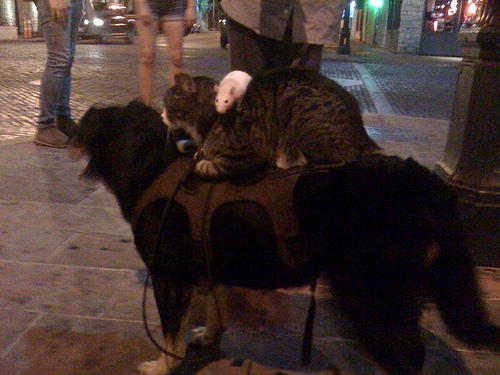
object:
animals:
[102, 66, 473, 320]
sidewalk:
[0, 269, 325, 374]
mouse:
[208, 69, 252, 115]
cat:
[156, 64, 379, 180]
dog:
[45, 95, 500, 375]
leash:
[144, 175, 197, 362]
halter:
[153, 177, 283, 215]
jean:
[34, 27, 67, 119]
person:
[23, 0, 100, 170]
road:
[345, 56, 451, 102]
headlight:
[80, 15, 104, 28]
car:
[80, 4, 140, 40]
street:
[0, 35, 216, 136]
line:
[346, 57, 391, 118]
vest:
[121, 156, 309, 247]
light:
[366, 0, 389, 17]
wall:
[363, 15, 391, 45]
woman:
[134, 0, 194, 107]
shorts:
[131, 2, 190, 23]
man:
[33, 0, 83, 151]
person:
[219, 4, 333, 63]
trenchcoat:
[221, 10, 350, 50]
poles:
[336, 6, 350, 59]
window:
[430, 11, 465, 34]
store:
[400, 0, 499, 63]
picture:
[25, 10, 489, 318]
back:
[160, 167, 375, 190]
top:
[148, 30, 424, 85]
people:
[27, 0, 93, 148]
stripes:
[299, 96, 328, 128]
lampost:
[422, 10, 499, 204]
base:
[432, 66, 498, 188]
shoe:
[30, 116, 76, 153]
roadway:
[321, 61, 471, 111]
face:
[154, 90, 180, 134]